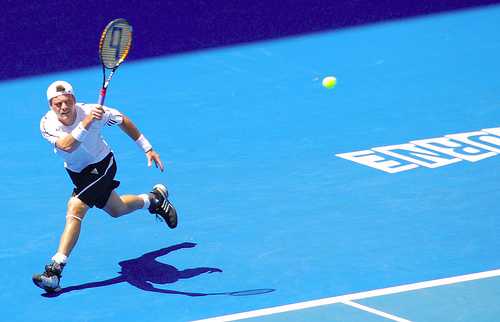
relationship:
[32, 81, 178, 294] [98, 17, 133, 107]
man holding racket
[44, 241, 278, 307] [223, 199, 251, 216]
shadow on ground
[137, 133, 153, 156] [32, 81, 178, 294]
band on man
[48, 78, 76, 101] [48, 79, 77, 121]
cap on head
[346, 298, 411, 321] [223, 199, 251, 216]
line on ground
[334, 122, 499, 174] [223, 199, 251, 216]
letters on ground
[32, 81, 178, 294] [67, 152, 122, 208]
man wearing shorts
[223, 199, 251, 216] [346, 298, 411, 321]
ground has line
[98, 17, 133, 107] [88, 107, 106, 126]
racket in hand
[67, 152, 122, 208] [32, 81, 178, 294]
shorts on man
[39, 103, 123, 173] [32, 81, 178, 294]
shirt on man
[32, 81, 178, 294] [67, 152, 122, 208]
man in shorts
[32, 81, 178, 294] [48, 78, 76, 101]
man in cap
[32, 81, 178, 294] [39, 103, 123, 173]
man in shirt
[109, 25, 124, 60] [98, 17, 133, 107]
logo on racket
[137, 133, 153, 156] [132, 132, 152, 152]
wrist wearing band